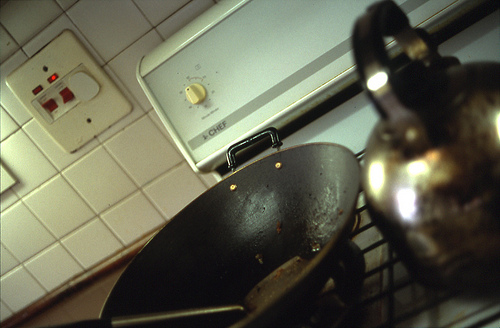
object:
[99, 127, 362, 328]
pan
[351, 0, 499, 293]
kettle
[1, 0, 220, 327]
tiles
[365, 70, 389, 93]
light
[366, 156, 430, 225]
light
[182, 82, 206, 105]
knob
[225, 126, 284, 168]
handle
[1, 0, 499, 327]
kitchen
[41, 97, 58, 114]
switch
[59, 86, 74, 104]
switch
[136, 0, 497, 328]
stove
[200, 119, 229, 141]
brand name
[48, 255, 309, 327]
spatula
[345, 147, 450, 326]
burner grates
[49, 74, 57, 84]
light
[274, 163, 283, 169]
screw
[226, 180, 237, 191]
screw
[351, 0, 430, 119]
handle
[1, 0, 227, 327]
wall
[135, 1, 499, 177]
back panel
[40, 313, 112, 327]
handle